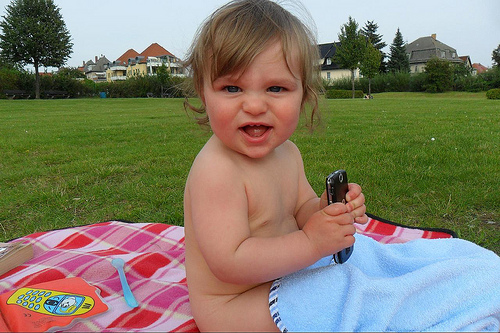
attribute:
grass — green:
[1, 93, 498, 251]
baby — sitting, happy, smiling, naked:
[187, 4, 363, 332]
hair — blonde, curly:
[171, 8, 325, 133]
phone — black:
[323, 175, 359, 269]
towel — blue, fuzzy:
[271, 227, 499, 333]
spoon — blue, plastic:
[111, 252, 140, 310]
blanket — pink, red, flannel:
[5, 223, 499, 332]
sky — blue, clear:
[3, 1, 499, 79]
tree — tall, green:
[7, 2, 65, 106]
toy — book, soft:
[3, 273, 111, 332]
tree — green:
[336, 20, 362, 106]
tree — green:
[362, 41, 384, 103]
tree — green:
[389, 29, 412, 93]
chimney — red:
[432, 34, 438, 42]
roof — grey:
[398, 35, 455, 52]